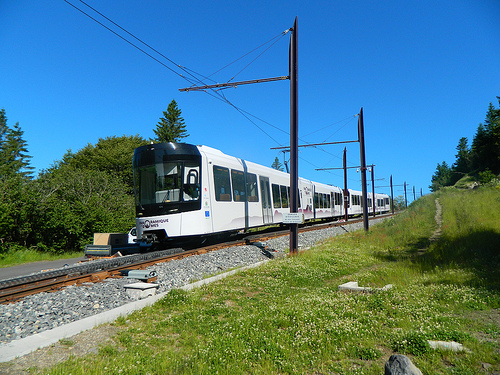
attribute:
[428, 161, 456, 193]
tree — on far right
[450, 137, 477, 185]
tree — on far right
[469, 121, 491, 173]
tree — on far right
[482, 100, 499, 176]
tree — on far right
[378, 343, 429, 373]
log — small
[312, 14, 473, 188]
sky — blue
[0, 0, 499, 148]
sky — clear, blue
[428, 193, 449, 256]
strip — bare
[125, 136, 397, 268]
train — white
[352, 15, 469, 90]
sky — blue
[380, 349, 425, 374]
rock — big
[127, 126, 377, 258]
train — rolling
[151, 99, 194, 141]
trees — to the side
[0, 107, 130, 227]
trees — to the side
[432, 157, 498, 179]
trees — to the side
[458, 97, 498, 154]
trees — to the side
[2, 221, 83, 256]
trees — to the side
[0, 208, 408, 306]
tracks — rail road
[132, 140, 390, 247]
train — first, car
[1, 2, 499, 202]
sky — clear, blue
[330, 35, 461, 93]
sky — blue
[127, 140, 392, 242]
bus — white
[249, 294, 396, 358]
flowers — wild